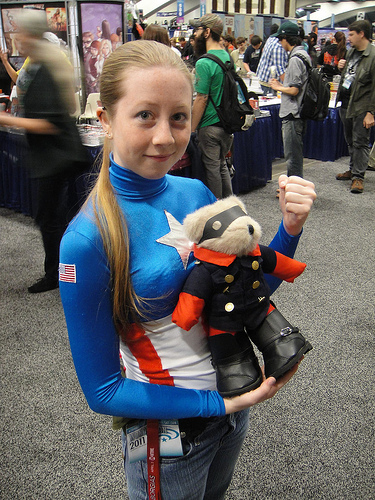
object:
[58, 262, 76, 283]
flag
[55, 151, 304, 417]
shirt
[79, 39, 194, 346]
hair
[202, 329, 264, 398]
boot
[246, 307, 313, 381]
boot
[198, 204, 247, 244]
mask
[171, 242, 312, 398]
clothes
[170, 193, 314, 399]
teddy bear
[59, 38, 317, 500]
girl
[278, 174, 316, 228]
fist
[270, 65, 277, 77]
drink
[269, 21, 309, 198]
boy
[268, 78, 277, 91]
hands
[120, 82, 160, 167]
complexion